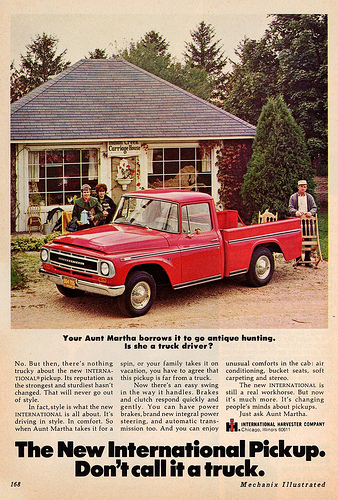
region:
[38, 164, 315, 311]
Red pickup truck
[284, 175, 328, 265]
Man holding a chair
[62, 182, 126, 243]
Two women holding antiques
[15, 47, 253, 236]
antique store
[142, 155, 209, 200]
Carousel horse in a window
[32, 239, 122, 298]
Front end of a International Pickup truck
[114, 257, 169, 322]
Tire of a truck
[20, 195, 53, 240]
antique chair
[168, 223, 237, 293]
Door of a red pickup truck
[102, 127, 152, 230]
Door of an antique store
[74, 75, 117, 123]
Black roof of the house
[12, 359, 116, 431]
Two paragraphs of text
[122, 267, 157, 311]
Left front wheel of red truck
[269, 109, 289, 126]
Small part of a Christmas tree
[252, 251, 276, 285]
Left back wheel of truck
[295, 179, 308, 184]
White hat of the man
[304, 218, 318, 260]
Wooden chair that the man is holding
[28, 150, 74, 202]
One of the windows for the house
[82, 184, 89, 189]
Gray hair of the lady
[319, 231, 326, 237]
Small patch of green grass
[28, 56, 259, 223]
a small house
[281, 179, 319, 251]
a man behind a chair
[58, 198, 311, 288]
an old red pickup truck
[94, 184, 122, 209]
a redhaired woman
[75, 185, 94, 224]
a grayhaired woman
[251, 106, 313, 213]
an evergreen tree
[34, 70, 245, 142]
a house's gray roof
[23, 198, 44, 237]
a chair leaning against a house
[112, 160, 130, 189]
a planter mounted on a house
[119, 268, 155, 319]
a truck's left front tire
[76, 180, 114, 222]
Two women outside an antique shop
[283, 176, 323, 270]
A shop owner loading his sold product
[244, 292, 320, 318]
Gravel on a dirt road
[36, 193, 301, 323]
An international pickup truck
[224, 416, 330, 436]
International Harvester Company logo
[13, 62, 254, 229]
Antique shop with door and windows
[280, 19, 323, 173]
Pine trees in a line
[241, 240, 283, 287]
A truck tire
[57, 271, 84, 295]
The front license plate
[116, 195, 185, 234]
Front windshield of a truck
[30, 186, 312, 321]
A older red truck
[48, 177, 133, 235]
A couple of women holding items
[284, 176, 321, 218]
A older man in a hat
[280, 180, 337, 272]
A older man holding a chair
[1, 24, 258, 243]
A little cottage-like shop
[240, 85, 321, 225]
A tall green tree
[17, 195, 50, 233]
A wooden chair leaning against a building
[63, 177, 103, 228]
A woman in green holding her purchases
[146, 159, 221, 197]
A horse statue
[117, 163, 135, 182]
A pink flowering plant